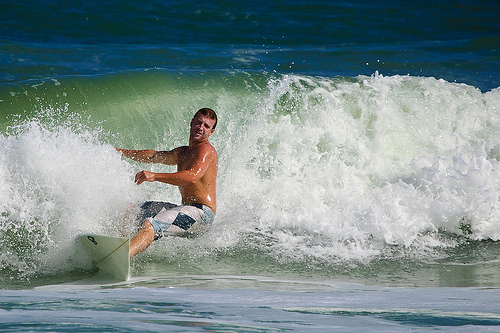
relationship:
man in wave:
[78, 108, 217, 281] [0, 65, 499, 288]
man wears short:
[78, 108, 217, 281] [139, 201, 215, 241]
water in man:
[268, 64, 415, 271] [78, 108, 217, 281]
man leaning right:
[78, 108, 217, 281] [437, 3, 495, 332]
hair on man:
[191, 97, 221, 121] [115, 97, 230, 263]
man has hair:
[115, 97, 230, 263] [188, 105, 219, 133]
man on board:
[78, 108, 217, 281] [81, 234, 130, 280]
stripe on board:
[91, 234, 127, 265] [71, 232, 131, 280]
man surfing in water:
[78, 108, 217, 281] [200, 251, 498, 331]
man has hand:
[78, 108, 217, 281] [134, 166, 157, 188]